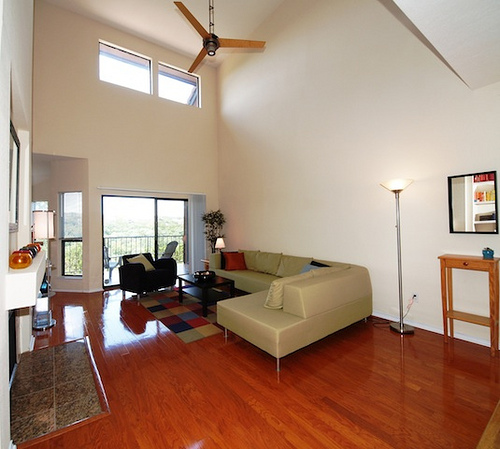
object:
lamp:
[215, 238, 227, 249]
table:
[201, 259, 213, 271]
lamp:
[380, 178, 414, 193]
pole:
[394, 194, 405, 325]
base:
[390, 319, 416, 334]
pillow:
[224, 251, 248, 271]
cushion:
[243, 248, 311, 279]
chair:
[117, 252, 177, 294]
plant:
[204, 210, 228, 254]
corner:
[201, 58, 239, 267]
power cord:
[373, 294, 418, 329]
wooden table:
[435, 249, 499, 356]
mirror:
[451, 175, 498, 233]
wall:
[215, 0, 500, 349]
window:
[98, 36, 205, 108]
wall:
[32, 4, 217, 293]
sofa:
[205, 243, 372, 357]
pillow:
[127, 253, 156, 272]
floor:
[19, 292, 498, 448]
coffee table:
[173, 267, 239, 316]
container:
[483, 246, 495, 259]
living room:
[3, 1, 499, 448]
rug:
[137, 290, 227, 344]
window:
[57, 190, 84, 279]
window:
[95, 191, 204, 287]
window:
[31, 199, 53, 268]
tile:
[54, 396, 108, 431]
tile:
[5, 388, 55, 426]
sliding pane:
[151, 194, 193, 268]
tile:
[53, 358, 90, 383]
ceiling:
[34, 1, 303, 72]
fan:
[164, 1, 269, 72]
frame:
[448, 171, 498, 234]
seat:
[144, 266, 170, 276]